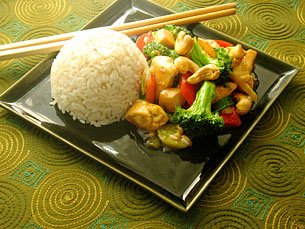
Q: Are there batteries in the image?
A: No, there are no batteries.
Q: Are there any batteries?
A: No, there are no batteries.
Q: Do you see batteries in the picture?
A: No, there are no batteries.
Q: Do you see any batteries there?
A: No, there are no batteries.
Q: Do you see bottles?
A: No, there are no bottles.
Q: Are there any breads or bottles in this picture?
A: No, there are no bottles or breads.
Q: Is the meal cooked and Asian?
A: Yes, the meal is cooked and asian.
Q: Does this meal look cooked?
A: Yes, the meal is cooked.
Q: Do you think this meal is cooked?
A: Yes, the meal is cooked.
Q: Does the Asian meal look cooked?
A: Yes, the meal is cooked.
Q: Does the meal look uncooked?
A: No, the meal is cooked.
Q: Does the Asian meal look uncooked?
A: No, the meal is cooked.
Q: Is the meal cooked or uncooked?
A: The meal is cooked.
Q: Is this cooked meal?
A: Yes, this is cooked meal.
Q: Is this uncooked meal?
A: No, this is cooked meal.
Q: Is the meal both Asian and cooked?
A: Yes, the meal is Asian and cooked.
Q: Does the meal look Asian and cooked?
A: Yes, the meal is Asian and cooked.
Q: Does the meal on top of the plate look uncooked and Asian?
A: No, the meal is Asian but cooked.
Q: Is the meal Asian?
A: Yes, the meal is asian.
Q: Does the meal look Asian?
A: Yes, the meal is asian.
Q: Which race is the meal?
A: The meal is asian.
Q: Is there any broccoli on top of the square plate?
A: No, there is meal on top of the plate.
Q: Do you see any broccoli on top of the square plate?
A: No, there is meal on top of the plate.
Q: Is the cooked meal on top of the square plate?
A: Yes, the meal is on top of the plate.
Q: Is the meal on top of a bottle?
A: No, the meal is on top of the plate.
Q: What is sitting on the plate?
A: The meal is sitting on the plate.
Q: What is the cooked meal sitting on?
A: The meal is sitting on the plate.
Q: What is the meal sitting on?
A: The meal is sitting on the plate.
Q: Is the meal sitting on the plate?
A: Yes, the meal is sitting on the plate.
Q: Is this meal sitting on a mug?
A: No, the meal is sitting on the plate.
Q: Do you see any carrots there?
A: Yes, there is a carrot.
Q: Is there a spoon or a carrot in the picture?
A: Yes, there is a carrot.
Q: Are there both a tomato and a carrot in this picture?
A: No, there is a carrot but no tomatoes.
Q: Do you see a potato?
A: No, there are no potatoes.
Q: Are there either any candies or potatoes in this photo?
A: No, there are no potatoes or candies.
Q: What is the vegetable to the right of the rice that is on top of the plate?
A: The vegetable is a carrot.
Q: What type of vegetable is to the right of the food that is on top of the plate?
A: The vegetable is a carrot.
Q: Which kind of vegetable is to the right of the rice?
A: The vegetable is a carrot.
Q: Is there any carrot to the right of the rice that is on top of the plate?
A: Yes, there is a carrot to the right of the rice.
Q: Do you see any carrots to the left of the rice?
A: No, the carrot is to the right of the rice.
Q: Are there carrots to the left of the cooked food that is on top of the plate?
A: No, the carrot is to the right of the rice.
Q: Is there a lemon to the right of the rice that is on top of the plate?
A: No, there is a carrot to the right of the rice.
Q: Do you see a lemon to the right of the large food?
A: No, there is a carrot to the right of the rice.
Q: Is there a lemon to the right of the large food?
A: No, there is a carrot to the right of the rice.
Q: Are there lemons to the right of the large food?
A: No, there is a carrot to the right of the rice.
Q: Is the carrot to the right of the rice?
A: Yes, the carrot is to the right of the rice.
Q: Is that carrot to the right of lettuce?
A: No, the carrot is to the right of the rice.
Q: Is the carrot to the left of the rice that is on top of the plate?
A: No, the carrot is to the right of the rice.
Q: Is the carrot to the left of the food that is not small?
A: No, the carrot is to the right of the rice.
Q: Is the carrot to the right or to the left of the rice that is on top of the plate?
A: The carrot is to the right of the rice.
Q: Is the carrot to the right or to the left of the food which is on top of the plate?
A: The carrot is to the right of the rice.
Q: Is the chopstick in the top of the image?
A: Yes, the chopstick is in the top of the image.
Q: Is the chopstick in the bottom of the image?
A: No, the chopstick is in the top of the image.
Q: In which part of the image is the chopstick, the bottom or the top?
A: The chopstick is in the top of the image.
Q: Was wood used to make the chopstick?
A: Yes, the chopstick is made of wood.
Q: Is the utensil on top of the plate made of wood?
A: Yes, the chopstick is made of wood.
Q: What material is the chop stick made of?
A: The chop stick is made of wood.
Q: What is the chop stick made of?
A: The chop stick is made of wood.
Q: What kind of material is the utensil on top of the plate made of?
A: The chop stick is made of wood.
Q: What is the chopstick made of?
A: The chop stick is made of wood.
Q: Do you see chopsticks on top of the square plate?
A: Yes, there is a chopstick on top of the plate.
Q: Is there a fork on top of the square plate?
A: No, there is a chopstick on top of the plate.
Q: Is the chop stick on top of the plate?
A: Yes, the chop stick is on top of the plate.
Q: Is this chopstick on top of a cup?
A: No, the chopstick is on top of the plate.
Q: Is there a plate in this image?
A: Yes, there is a plate.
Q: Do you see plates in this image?
A: Yes, there is a plate.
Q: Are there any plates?
A: Yes, there is a plate.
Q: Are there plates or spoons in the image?
A: Yes, there is a plate.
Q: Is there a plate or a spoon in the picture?
A: Yes, there is a plate.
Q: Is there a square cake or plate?
A: Yes, there is a square plate.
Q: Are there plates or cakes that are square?
A: Yes, the plate is square.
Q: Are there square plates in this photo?
A: Yes, there is a square plate.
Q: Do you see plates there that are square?
A: Yes, there is a plate that is square.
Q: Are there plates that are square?
A: Yes, there is a plate that is square.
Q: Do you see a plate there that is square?
A: Yes, there is a plate that is square.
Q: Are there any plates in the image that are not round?
A: Yes, there is a square plate.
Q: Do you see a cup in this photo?
A: No, there are no cups.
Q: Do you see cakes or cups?
A: No, there are no cups or cakes.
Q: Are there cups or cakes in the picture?
A: No, there are no cups or cakes.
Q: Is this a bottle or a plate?
A: This is a plate.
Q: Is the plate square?
A: Yes, the plate is square.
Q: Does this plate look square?
A: Yes, the plate is square.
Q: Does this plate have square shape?
A: Yes, the plate is square.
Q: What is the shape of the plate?
A: The plate is square.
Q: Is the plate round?
A: No, the plate is square.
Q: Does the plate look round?
A: No, the plate is square.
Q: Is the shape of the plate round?
A: No, the plate is square.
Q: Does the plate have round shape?
A: No, the plate is square.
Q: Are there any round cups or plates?
A: No, there is a plate but it is square.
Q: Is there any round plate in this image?
A: No, there is a plate but it is square.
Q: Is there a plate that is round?
A: No, there is a plate but it is square.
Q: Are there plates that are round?
A: No, there is a plate but it is square.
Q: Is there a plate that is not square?
A: No, there is a plate but it is square.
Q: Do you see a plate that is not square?
A: No, there is a plate but it is square.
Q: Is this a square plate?
A: Yes, this is a square plate.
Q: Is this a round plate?
A: No, this is a square plate.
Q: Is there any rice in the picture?
A: Yes, there is rice.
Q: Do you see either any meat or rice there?
A: Yes, there is rice.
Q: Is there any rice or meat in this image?
A: Yes, there is rice.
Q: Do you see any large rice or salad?
A: Yes, there is large rice.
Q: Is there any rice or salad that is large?
A: Yes, the rice is large.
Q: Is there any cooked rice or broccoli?
A: Yes, there is cooked rice.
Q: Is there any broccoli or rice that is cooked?
A: Yes, the rice is cooked.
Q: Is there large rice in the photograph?
A: Yes, there is large rice.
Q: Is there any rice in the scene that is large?
A: Yes, there is rice that is large.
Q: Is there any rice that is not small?
A: Yes, there is large rice.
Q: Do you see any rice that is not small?
A: Yes, there is large rice.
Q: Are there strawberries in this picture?
A: No, there are no strawberries.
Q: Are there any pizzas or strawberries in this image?
A: No, there are no strawberries or pizzas.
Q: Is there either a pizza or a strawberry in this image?
A: No, there are no strawberries or pizzas.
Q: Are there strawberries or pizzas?
A: No, there are no strawberries or pizzas.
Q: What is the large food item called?
A: The food item is rice.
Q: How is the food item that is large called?
A: The food item is rice.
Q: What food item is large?
A: The food item is rice.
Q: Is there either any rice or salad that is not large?
A: No, there is rice but it is large.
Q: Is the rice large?
A: Yes, the rice is large.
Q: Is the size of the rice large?
A: Yes, the rice is large.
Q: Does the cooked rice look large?
A: Yes, the rice is large.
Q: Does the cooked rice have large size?
A: Yes, the rice is large.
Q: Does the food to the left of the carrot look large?
A: Yes, the rice is large.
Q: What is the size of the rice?
A: The rice is large.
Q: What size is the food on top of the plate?
A: The rice is large.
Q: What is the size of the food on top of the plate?
A: The rice is large.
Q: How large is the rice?
A: The rice is large.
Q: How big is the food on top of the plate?
A: The rice is large.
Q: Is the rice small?
A: No, the rice is large.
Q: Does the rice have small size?
A: No, the rice is large.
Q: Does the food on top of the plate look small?
A: No, the rice is large.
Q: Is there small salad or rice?
A: No, there is rice but it is large.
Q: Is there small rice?
A: No, there is rice but it is large.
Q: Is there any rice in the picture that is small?
A: No, there is rice but it is large.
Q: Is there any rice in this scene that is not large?
A: No, there is rice but it is large.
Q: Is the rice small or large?
A: The rice is large.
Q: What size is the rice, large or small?
A: The rice is large.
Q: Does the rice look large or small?
A: The rice is large.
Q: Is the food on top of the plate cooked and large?
A: Yes, the rice is cooked and large.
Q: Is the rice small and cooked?
A: No, the rice is cooked but large.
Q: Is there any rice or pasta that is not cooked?
A: No, there is rice but it is cooked.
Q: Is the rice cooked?
A: Yes, the rice is cooked.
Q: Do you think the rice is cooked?
A: Yes, the rice is cooked.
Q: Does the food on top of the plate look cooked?
A: Yes, the rice is cooked.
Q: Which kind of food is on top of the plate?
A: The food is rice.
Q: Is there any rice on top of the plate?
A: Yes, there is rice on top of the plate.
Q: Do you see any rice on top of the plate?
A: Yes, there is rice on top of the plate.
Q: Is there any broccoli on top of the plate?
A: No, there is rice on top of the plate.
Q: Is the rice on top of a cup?
A: No, the rice is on top of the plate.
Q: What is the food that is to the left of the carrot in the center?
A: The food is rice.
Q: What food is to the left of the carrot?
A: The food is rice.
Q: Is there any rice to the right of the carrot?
A: No, the rice is to the left of the carrot.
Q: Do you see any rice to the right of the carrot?
A: No, the rice is to the left of the carrot.